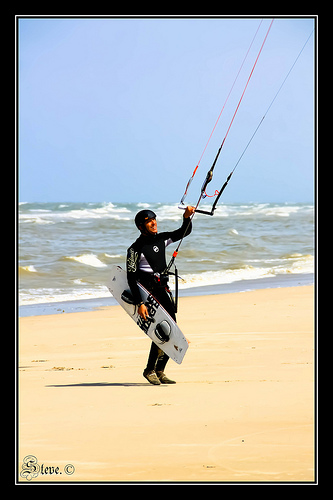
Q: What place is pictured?
A: It is a beach.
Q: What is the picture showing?
A: It is showing a beach.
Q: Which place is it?
A: It is a beach.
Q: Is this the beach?
A: Yes, it is the beach.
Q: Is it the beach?
A: Yes, it is the beach.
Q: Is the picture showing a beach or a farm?
A: It is showing a beach.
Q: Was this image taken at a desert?
A: No, the picture was taken in a beach.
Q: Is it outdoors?
A: Yes, it is outdoors.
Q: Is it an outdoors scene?
A: Yes, it is outdoors.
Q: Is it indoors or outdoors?
A: It is outdoors.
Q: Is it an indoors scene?
A: No, it is outdoors.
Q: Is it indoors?
A: No, it is outdoors.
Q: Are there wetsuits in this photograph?
A: Yes, there is a wetsuit.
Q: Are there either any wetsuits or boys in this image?
A: Yes, there is a wetsuit.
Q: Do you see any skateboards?
A: No, there are no skateboards.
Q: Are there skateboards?
A: No, there are no skateboards.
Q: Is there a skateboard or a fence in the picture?
A: No, there are no skateboards or fences.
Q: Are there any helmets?
A: Yes, there is a helmet.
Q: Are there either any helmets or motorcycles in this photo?
A: Yes, there is a helmet.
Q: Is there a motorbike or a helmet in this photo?
A: Yes, there is a helmet.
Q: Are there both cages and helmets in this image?
A: No, there is a helmet but no cages.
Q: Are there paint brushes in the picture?
A: No, there are no paint brushes.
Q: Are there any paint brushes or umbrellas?
A: No, there are no paint brushes or umbrellas.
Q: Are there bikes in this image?
A: No, there are no bikes.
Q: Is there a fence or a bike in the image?
A: No, there are no bikes or fences.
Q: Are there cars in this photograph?
A: No, there are no cars.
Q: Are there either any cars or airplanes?
A: No, there are no cars or airplanes.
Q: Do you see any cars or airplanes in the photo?
A: No, there are no cars or airplanes.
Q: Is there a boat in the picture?
A: No, there are no boats.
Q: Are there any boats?
A: No, there are no boats.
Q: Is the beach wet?
A: Yes, the beach is wet.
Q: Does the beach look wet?
A: Yes, the beach is wet.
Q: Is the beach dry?
A: No, the beach is wet.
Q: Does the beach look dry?
A: No, the beach is wet.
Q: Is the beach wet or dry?
A: The beach is wet.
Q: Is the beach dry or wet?
A: The beach is wet.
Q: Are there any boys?
A: No, there are no boys.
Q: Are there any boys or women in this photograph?
A: No, there are no boys or women.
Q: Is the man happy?
A: Yes, the man is happy.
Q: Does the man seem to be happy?
A: Yes, the man is happy.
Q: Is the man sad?
A: No, the man is happy.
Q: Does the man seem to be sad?
A: No, the man is happy.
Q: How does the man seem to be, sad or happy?
A: The man is happy.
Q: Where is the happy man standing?
A: The man is standing on the beach.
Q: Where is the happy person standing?
A: The man is standing on the beach.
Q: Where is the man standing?
A: The man is standing on the beach.